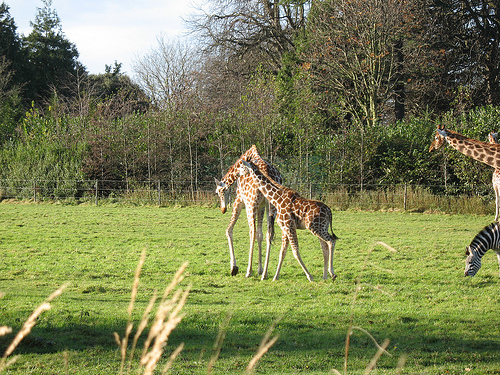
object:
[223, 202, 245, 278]
leg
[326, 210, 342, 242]
tail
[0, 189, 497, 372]
grass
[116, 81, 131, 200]
tree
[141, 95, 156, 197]
tree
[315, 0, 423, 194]
tree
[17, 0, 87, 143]
tree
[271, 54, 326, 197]
tree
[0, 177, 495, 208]
enclosure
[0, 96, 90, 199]
trees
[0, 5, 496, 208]
background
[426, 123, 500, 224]
giraffe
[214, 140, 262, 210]
neck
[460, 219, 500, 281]
animals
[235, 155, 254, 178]
heads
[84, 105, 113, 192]
trees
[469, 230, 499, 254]
stripes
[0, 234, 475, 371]
grasses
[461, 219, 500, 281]
zebra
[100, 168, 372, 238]
front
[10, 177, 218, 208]
fence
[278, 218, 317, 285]
leg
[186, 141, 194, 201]
trunks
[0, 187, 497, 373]
area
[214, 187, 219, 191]
marking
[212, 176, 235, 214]
head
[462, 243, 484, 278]
head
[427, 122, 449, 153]
head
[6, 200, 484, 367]
field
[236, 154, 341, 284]
animal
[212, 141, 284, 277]
animal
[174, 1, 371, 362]
center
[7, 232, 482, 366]
plants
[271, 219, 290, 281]
leg